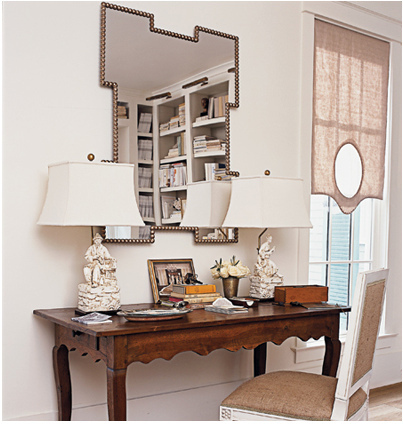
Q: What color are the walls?
A: White.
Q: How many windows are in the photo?
A: One.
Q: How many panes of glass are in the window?
A: Twelve.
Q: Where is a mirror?
A: On the wall.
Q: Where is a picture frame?
A: On table.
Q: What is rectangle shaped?
A: The table.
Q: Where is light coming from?
A: Window.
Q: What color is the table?
A: Brown.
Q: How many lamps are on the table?
A: Two.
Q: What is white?
A: Lamp shades.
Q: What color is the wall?
A: White.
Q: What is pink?
A: Window shade.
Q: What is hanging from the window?
A: Curtain.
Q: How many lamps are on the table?
A: Two.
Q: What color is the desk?
A: Brown.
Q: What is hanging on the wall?
A: Mirror.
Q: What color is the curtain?
A: Tan.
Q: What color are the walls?
A: White.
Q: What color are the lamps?
A: White.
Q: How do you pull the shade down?
A: Pull from the hole.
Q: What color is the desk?
A: Brown.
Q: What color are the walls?
A: White.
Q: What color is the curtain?
A: Beige.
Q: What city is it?
A: Boston.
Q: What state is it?
A: Massachusetts.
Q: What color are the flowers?
A: White.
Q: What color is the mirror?
A: Gold and shiny.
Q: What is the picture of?
A: A desk.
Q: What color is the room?
A: White.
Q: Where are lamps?
A: On the desk.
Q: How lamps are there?
A: Two.